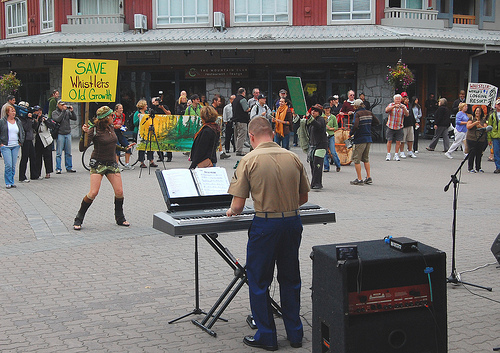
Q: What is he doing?
A: Playing.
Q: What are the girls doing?
A: Dancing.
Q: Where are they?
A: In front of building.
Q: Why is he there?
A: To play.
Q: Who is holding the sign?
A: The girl.